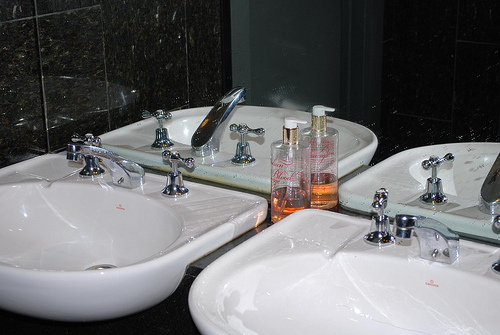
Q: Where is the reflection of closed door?
A: In mirror.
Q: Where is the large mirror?
A: Behind sinks.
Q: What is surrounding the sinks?
A: Black counter top.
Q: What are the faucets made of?
A: Silver.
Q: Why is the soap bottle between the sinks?
A: To wash with.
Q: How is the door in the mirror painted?
A: White.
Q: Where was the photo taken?
A: Bathroom.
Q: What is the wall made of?
A: Black tiles.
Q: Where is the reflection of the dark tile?
A: In mirror.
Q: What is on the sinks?
A: Faucets.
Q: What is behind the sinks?
A: Mirror.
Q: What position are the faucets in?
A: Off.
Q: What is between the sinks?
A: Soap.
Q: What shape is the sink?
A: Circular.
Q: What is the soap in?
A: Hand pump.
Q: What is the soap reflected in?
A: Mirror.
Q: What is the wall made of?
A: Marble.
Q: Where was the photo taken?
A: Bathroom.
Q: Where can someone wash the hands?
A: Sinks.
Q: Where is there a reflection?
A: In mirror.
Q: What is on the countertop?
A: Soap.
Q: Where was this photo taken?
A: A bathroom.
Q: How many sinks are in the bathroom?
A: Two.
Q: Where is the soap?
A: In between the two sinks.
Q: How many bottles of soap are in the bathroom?
A: One.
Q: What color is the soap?
A: Orange.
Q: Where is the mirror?
A: Behind the sinks.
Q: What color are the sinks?
A: White.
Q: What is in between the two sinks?
A: Soap.